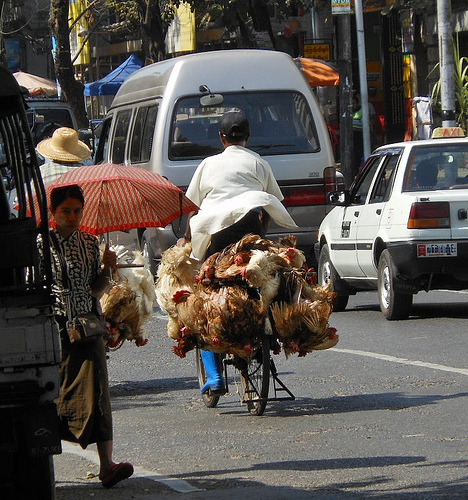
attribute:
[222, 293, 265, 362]
chicken — dead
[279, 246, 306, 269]
chicken — dead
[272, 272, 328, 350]
chicken — dead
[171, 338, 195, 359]
chicken — dead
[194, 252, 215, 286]
chicken — dead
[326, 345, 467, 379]
line — white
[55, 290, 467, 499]
road — grey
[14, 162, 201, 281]
umbrella — red, white, open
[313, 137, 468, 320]
car — white, taxi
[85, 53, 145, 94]
umbrella — blue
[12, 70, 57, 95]
umbrella — tan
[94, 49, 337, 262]
van — grey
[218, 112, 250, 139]
hat — black, trucker hat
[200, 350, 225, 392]
boot — blue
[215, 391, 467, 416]
shadow — pointed right, cast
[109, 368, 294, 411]
shadow — pointed right, cast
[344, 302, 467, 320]
shadow — pointed right, cast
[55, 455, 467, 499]
shadow — pointed right, cast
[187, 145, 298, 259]
shirt — white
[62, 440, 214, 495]
line — white